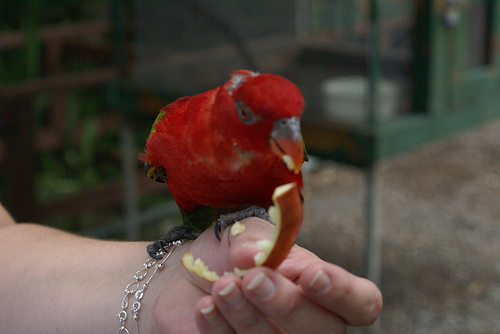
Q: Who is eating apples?
A: The bird.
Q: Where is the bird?
A: On a hand.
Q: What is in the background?
A: A birdcage.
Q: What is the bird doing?
A: Eating.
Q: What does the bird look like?
A: The bird is red.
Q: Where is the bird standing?
A: On the person's hand.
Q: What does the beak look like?
A: The beak is orange.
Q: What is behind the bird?
A: A green cage.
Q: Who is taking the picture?
A: A photographer.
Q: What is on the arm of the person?
A: A bracelet.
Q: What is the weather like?
A: Cloudy and warm.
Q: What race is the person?
A: White.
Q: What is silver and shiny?
A: Bracelet.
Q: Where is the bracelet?
A: Woman's wrist.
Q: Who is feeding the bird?
A: Woman with bracelet.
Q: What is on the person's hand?
A: A bird.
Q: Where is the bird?
A: On the person's hand.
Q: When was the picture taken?
A: Daytime.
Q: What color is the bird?
A: Red.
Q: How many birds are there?
A: One.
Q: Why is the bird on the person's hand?
A: It is eating.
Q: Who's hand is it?
A: The woman's.